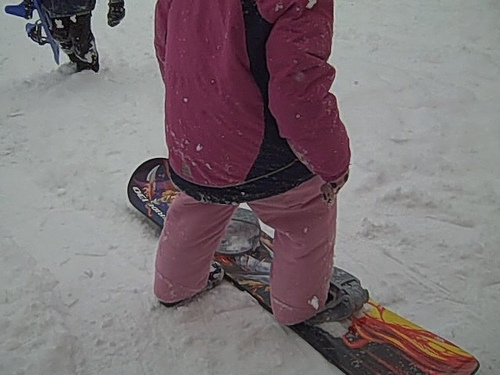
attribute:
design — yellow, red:
[339, 300, 473, 372]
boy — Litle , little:
[147, 1, 353, 328]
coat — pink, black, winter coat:
[136, 19, 391, 197]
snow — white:
[363, 67, 480, 190]